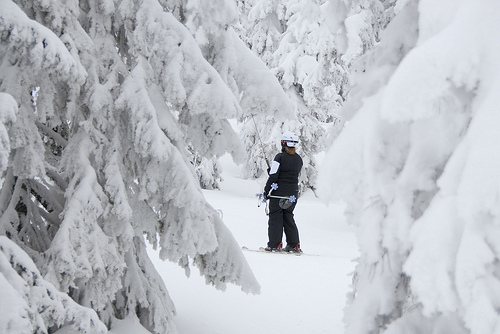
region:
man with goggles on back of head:
[255, 121, 310, 261]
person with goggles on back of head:
[249, 121, 311, 265]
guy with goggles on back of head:
[249, 116, 311, 261]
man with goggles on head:
[257, 128, 305, 258]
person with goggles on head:
[244, 126, 309, 256]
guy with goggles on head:
[251, 127, 314, 260]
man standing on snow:
[253, 118, 310, 260]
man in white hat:
[249, 119, 316, 261]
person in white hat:
[254, 121, 307, 278]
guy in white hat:
[255, 118, 313, 266]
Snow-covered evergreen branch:
[117, 101, 257, 301]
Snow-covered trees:
[37, 38, 257, 316]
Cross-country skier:
[225, 130, 330, 278]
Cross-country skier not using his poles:
[232, 122, 328, 267]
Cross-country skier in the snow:
[239, 125, 332, 269]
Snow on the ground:
[282, 263, 342, 333]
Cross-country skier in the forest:
[200, 93, 346, 286]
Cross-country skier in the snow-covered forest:
[234, 93, 341, 266]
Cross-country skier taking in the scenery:
[227, 123, 333, 268]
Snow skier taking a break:
[234, 124, 317, 281]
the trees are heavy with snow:
[0, 0, 499, 332]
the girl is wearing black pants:
[265, 183, 302, 249]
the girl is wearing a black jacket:
[263, 148, 310, 200]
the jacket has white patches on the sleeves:
[267, 158, 279, 176]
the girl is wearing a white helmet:
[281, 127, 301, 150]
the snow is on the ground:
[83, 143, 359, 332]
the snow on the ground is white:
[116, 152, 366, 332]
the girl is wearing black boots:
[261, 237, 306, 252]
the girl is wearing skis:
[240, 241, 341, 260]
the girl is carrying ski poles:
[251, 182, 297, 214]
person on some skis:
[234, 124, 330, 275]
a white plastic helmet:
[280, 128, 304, 148]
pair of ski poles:
[247, 181, 309, 214]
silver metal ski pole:
[249, 190, 301, 202]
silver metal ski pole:
[255, 179, 279, 206]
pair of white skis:
[234, 238, 339, 261]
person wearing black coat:
[250, 126, 315, 261]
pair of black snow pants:
[261, 189, 301, 256]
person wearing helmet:
[234, 125, 320, 274]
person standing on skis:
[249, 130, 313, 260]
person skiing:
[244, 128, 317, 253]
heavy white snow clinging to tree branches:
[1, 2, 491, 330]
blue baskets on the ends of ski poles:
[270, 181, 297, 203]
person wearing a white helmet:
[279, 129, 300, 149]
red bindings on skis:
[273, 240, 302, 252]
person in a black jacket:
[262, 145, 308, 199]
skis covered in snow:
[238, 243, 325, 261]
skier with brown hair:
[279, 135, 302, 161]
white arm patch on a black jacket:
[268, 158, 281, 176]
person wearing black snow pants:
[266, 192, 301, 251]